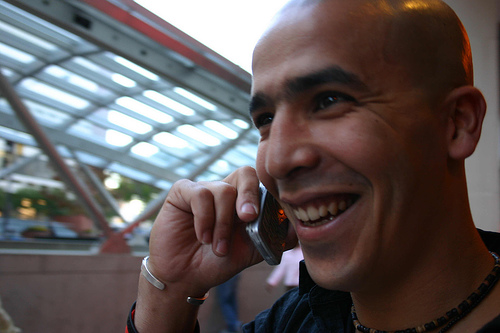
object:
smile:
[267, 180, 381, 240]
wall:
[0, 250, 123, 332]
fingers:
[222, 162, 262, 223]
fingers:
[206, 173, 241, 257]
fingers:
[173, 177, 214, 244]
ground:
[334, 193, 364, 220]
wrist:
[136, 254, 208, 317]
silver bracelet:
[135, 254, 210, 307]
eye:
[250, 108, 279, 128]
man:
[134, 10, 497, 327]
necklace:
[417, 265, 487, 332]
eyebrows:
[291, 66, 373, 88]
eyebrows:
[243, 87, 276, 107]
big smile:
[269, 186, 375, 233]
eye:
[300, 81, 368, 131]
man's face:
[230, 65, 359, 260]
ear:
[448, 85, 486, 160]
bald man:
[123, 0, 498, 331]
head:
[249, 0, 484, 296]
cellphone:
[243, 182, 290, 266]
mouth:
[281, 172, 369, 237]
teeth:
[275, 187, 353, 244]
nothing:
[184, 31, 216, 42]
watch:
[138, 255, 208, 305]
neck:
[350, 236, 497, 331]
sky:
[0, 0, 293, 228]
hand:
[139, 161, 306, 295]